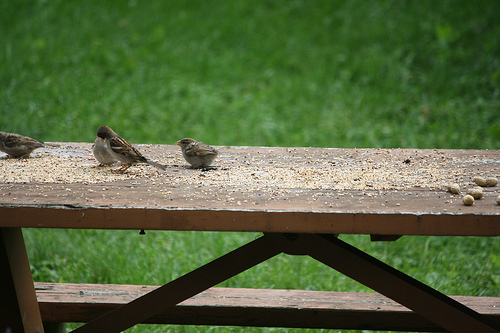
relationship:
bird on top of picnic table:
[177, 139, 218, 171] [0, 140, 500, 331]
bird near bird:
[97, 125, 166, 174] [177, 139, 218, 171]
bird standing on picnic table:
[97, 125, 166, 174] [0, 140, 500, 331]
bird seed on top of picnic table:
[0, 140, 500, 214] [0, 140, 500, 331]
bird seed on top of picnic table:
[85, 182, 90, 185] [0, 140, 500, 331]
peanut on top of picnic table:
[448, 183, 460, 193] [0, 140, 500, 331]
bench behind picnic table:
[30, 281, 499, 331] [0, 140, 500, 331]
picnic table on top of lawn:
[0, 140, 500, 331] [1, 0, 499, 332]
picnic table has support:
[0, 140, 500, 331] [71, 232, 499, 332]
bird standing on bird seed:
[92, 138, 120, 167] [104, 165, 107, 168]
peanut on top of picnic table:
[472, 176, 499, 187] [0, 140, 500, 331]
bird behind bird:
[92, 138, 120, 167] [97, 125, 166, 174]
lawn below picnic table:
[1, 0, 499, 332] [0, 140, 500, 331]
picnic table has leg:
[0, 140, 500, 331] [0, 228, 44, 332]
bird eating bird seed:
[177, 139, 218, 171] [173, 157, 177, 162]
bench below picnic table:
[30, 281, 499, 331] [0, 140, 500, 331]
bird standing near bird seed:
[0, 132, 47, 160] [7, 158, 11, 162]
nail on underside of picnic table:
[140, 230, 147, 235] [0, 140, 500, 331]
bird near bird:
[97, 125, 166, 174] [92, 138, 120, 167]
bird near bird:
[177, 139, 218, 171] [97, 125, 166, 174]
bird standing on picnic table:
[0, 132, 47, 160] [0, 140, 500, 331]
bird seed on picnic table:
[0, 140, 500, 214] [0, 140, 500, 331]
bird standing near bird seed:
[97, 125, 166, 174] [126, 174, 131, 179]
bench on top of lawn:
[30, 281, 499, 331] [1, 0, 499, 332]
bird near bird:
[92, 138, 120, 167] [0, 132, 47, 160]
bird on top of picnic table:
[92, 138, 120, 167] [0, 140, 500, 331]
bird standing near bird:
[97, 125, 166, 174] [92, 138, 120, 167]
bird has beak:
[177, 139, 218, 171] [178, 140, 184, 147]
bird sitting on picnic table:
[92, 138, 120, 167] [0, 140, 500, 331]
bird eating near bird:
[97, 125, 166, 174] [92, 138, 120, 167]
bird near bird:
[0, 132, 47, 160] [92, 138, 120, 167]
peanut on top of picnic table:
[463, 195, 474, 205] [0, 140, 500, 331]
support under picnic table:
[71, 232, 499, 332] [0, 140, 500, 331]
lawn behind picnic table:
[1, 0, 499, 332] [0, 140, 500, 331]